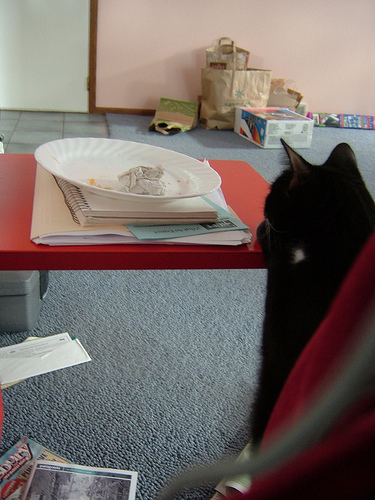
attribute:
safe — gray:
[2, 267, 51, 330]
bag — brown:
[198, 22, 311, 135]